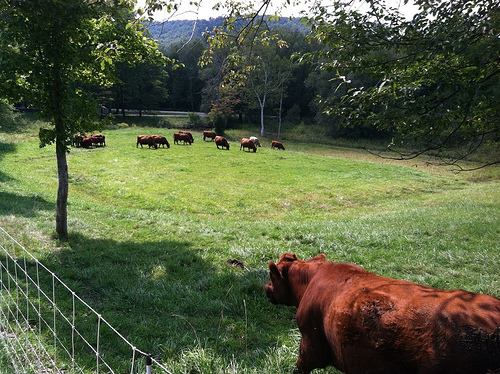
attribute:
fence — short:
[1, 221, 183, 371]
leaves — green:
[88, 9, 130, 64]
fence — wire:
[6, 254, 121, 369]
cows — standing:
[69, 127, 288, 154]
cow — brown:
[128, 118, 183, 163]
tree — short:
[7, 1, 119, 238]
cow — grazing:
[270, 140, 285, 150]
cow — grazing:
[213, 133, 230, 150]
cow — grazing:
[201, 130, 217, 141]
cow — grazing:
[239, 137, 258, 153]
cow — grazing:
[174, 131, 194, 145]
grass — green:
[123, 168, 323, 245]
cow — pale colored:
[246, 133, 262, 148]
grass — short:
[1, 107, 498, 369]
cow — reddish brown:
[230, 258, 490, 365]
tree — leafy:
[3, 4, 190, 241]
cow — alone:
[230, 219, 459, 359]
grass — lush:
[294, 162, 327, 203]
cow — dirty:
[262, 252, 498, 372]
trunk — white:
[251, 72, 271, 132]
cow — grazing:
[135, 133, 159, 152]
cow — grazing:
[168, 130, 192, 147]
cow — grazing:
[236, 133, 257, 153]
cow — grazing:
[76, 137, 92, 150]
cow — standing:
[94, 133, 103, 142]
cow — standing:
[268, 138, 287, 151]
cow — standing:
[211, 133, 230, 149]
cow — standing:
[200, 129, 220, 141]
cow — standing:
[152, 137, 172, 149]